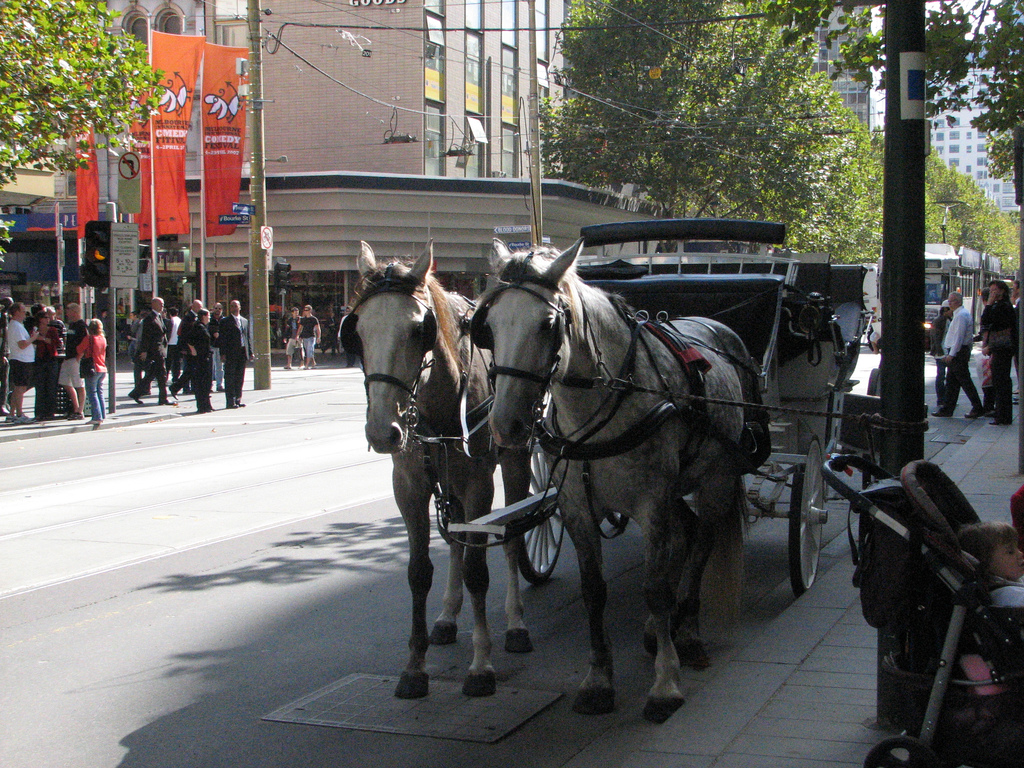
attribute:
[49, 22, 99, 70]
leaves — green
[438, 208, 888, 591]
carriage — black and white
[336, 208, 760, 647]
horse — standing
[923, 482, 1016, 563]
child — sitting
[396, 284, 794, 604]
horse — tied up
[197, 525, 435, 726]
shadows — underneath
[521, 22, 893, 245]
tree — green, leafy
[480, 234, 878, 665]
carriage — white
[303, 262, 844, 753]
horse — white, pulling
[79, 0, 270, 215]
banners — orange, large, white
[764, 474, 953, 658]
stroller — black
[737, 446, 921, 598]
wheel — black, white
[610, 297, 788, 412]
cloth — red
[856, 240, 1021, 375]
bus — white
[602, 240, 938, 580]
carriage — black, pulled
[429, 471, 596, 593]
bar — white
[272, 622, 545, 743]
panel — silver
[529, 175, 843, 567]
carriage — white, drawn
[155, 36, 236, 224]
banners — large, orange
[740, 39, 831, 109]
leaf — yellow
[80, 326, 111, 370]
jacket — pink